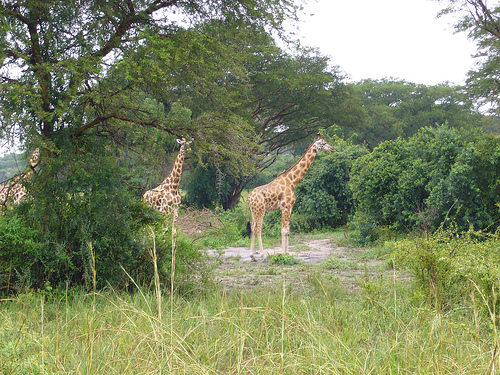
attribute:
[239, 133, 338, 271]
girafee — standing, tall, colored, white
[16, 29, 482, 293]
forrest — green, leafy, crowded, brown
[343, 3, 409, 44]
sky — grey, clear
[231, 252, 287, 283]
ground — dirty, green, grown, grassy